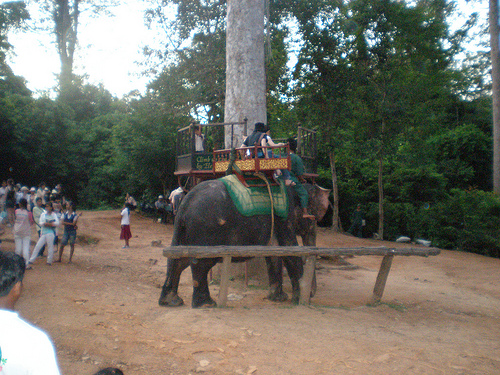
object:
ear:
[308, 184, 331, 223]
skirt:
[119, 224, 132, 239]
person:
[32, 197, 48, 258]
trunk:
[225, 0, 267, 144]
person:
[35, 182, 47, 205]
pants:
[28, 234, 55, 266]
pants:
[14, 234, 31, 268]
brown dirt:
[0, 208, 497, 374]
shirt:
[0, 309, 61, 375]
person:
[285, 137, 319, 221]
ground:
[283, 308, 360, 360]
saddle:
[212, 141, 292, 188]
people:
[13, 197, 36, 270]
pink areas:
[24, 267, 146, 312]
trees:
[0, 77, 43, 185]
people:
[189, 123, 205, 153]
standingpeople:
[4, 178, 17, 227]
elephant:
[157, 174, 332, 309]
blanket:
[218, 169, 290, 225]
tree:
[291, 0, 458, 241]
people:
[28, 203, 59, 266]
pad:
[219, 173, 289, 223]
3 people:
[239, 122, 316, 223]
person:
[119, 202, 133, 249]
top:
[207, 173, 287, 182]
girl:
[53, 199, 83, 263]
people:
[242, 125, 285, 159]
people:
[238, 122, 296, 187]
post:
[158, 257, 191, 306]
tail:
[158, 222, 180, 305]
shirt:
[120, 208, 130, 225]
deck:
[173, 168, 293, 177]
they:
[184, 121, 317, 222]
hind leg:
[191, 258, 217, 309]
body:
[193, 183, 296, 247]